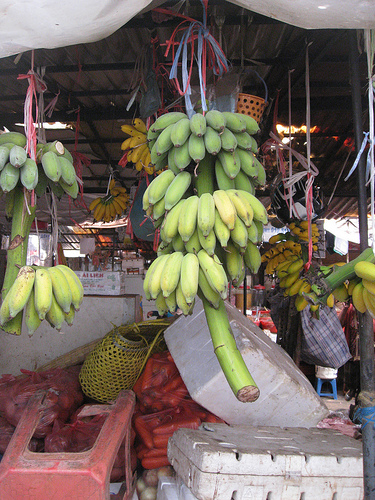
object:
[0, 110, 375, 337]
bananas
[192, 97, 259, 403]
stalk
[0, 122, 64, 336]
stalk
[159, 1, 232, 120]
ribbon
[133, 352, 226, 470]
carrots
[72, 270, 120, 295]
sign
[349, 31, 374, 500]
beams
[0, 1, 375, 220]
ceiling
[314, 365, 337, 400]
seat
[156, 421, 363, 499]
crate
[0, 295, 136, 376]
wall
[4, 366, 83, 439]
bag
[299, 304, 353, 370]
bag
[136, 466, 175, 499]
onions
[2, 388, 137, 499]
step stool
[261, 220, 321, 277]
menu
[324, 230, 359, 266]
wall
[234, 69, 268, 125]
basket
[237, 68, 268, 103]
blue handle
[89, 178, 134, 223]
bunches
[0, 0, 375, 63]
net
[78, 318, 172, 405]
bag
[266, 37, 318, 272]
ribbon